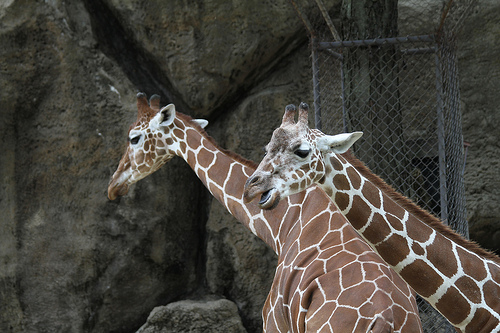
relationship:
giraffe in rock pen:
[104, 84, 430, 332] [0, 0, 497, 331]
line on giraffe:
[393, 230, 450, 277] [244, 99, 498, 331]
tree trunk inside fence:
[338, 9, 429, 247] [295, 30, 465, 214]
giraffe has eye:
[104, 84, 430, 332] [288, 139, 318, 169]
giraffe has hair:
[244, 99, 498, 331] [350, 148, 497, 258]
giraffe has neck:
[244, 99, 498, 331] [322, 132, 485, 332]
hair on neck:
[350, 148, 497, 258] [322, 132, 485, 332]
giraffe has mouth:
[244, 99, 498, 331] [249, 172, 271, 215]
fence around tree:
[310, 41, 468, 326] [334, 2, 419, 212]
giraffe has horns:
[244, 99, 498, 331] [296, 102, 311, 123]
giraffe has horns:
[244, 99, 498, 331] [281, 102, 296, 124]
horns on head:
[296, 102, 311, 123] [241, 100, 364, 210]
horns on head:
[281, 102, 296, 124] [241, 100, 364, 210]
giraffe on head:
[244, 99, 498, 331] [241, 100, 364, 210]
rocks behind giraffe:
[15, 5, 305, 126] [104, 84, 430, 332]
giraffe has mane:
[104, 84, 430, 332] [188, 108, 275, 187]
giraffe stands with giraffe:
[104, 84, 430, 332] [244, 99, 498, 331]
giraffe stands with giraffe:
[244, 99, 498, 331] [104, 84, 430, 332]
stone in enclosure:
[144, 295, 239, 330] [3, 3, 498, 328]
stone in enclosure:
[0, 0, 303, 331] [3, 3, 498, 328]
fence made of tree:
[310, 41, 468, 168] [330, 7, 405, 160]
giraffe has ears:
[104, 84, 430, 332] [152, 99, 213, 134]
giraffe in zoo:
[244, 99, 498, 331] [4, 4, 496, 329]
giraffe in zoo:
[104, 84, 430, 332] [4, 4, 496, 329]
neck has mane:
[243, 106, 495, 294] [345, 147, 496, 265]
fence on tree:
[310, 41, 468, 326] [340, 2, 407, 196]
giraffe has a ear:
[244, 99, 498, 331] [315, 127, 364, 152]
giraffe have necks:
[104, 84, 430, 332] [180, 130, 495, 325]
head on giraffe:
[105, 81, 265, 249] [104, 84, 430, 332]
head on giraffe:
[241, 100, 364, 210] [244, 99, 498, 331]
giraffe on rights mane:
[244, 99, 498, 331] [344, 147, 495, 253]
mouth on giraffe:
[104, 173, 136, 207] [104, 84, 430, 332]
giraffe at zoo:
[244, 99, 498, 331] [7, 59, 475, 329]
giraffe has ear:
[104, 84, 430, 332] [143, 96, 179, 137]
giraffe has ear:
[244, 99, 498, 331] [180, 108, 215, 135]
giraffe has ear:
[244, 99, 498, 331] [317, 118, 372, 169]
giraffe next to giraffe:
[244, 99, 498, 331] [104, 84, 430, 332]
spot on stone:
[106, 83, 121, 100] [3, 5, 198, 325]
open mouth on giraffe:
[235, 177, 280, 216] [220, 102, 478, 312]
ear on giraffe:
[315, 127, 364, 152] [244, 99, 498, 331]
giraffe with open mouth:
[244, 99, 498, 331] [237, 172, 286, 212]